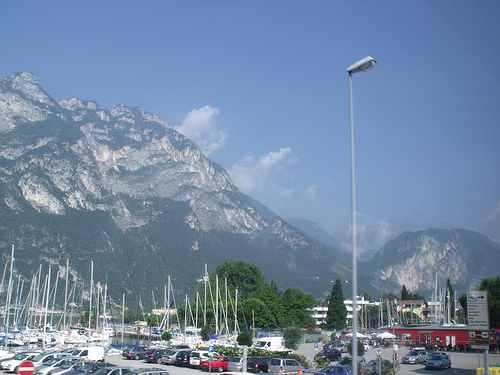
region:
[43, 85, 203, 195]
snowy mountain on the left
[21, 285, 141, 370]
boats in the water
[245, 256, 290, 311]
green trees next to mountain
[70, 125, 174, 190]
white snow on the mountain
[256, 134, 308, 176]
clouds in the sky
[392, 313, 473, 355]
red building on the ground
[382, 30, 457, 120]
blue sky above land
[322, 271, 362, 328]
green tree by itself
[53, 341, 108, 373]
many parked cars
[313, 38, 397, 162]
light hanging over the street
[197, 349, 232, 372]
a red compact car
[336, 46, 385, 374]
a tall street light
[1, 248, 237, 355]
many sailboats parked together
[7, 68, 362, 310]
big snow capped mountain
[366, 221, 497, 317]
smaller snowy mountain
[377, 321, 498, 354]
a long red building with white doors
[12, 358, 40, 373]
a red and white do not enter sign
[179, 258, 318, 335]
a group of green trees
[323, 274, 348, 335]
a single pointy evergreen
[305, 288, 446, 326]
a parking garage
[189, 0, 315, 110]
this is the sky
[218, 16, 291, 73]
the sky is blue in color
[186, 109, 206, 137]
these are the clouds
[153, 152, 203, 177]
these are the snows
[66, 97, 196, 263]
this is a mountain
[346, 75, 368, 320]
this is a pole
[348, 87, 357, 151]
the pole is white in color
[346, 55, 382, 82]
this is a lump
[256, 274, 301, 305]
this is a tree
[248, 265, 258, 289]
the tree has green leaves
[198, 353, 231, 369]
red car in parking area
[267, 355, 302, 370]
right side of gray suv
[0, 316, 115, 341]
sailboats in the harbor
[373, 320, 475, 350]
red building on the parking grounds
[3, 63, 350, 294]
beautiful tall rockside mountains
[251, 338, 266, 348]
front windshield of truck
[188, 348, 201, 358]
back rear window of van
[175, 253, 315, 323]
tall trees in the background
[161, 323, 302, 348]
decorative small trees on parking grounds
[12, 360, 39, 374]
red and white street sign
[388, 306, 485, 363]
a building is red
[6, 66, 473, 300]
mountains are covered with snow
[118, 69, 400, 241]
clouds are behind the mountain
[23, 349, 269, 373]
cars are in a parking lot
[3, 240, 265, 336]
boats are on the water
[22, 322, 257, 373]
cars are parked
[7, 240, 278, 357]
boats are in the dock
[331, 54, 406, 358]
street light is off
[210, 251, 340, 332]
trees are near the water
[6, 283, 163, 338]
lake is in front of the mountain